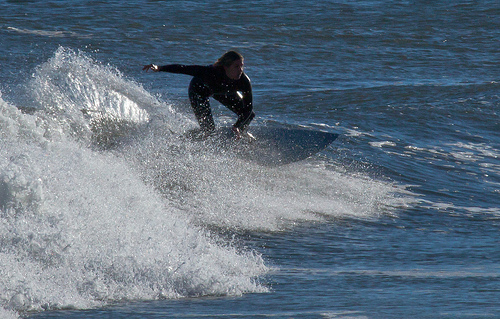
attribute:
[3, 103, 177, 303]
wave — breaking, large, white, splashing, frothy, crashing, swelling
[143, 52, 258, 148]
person — surfing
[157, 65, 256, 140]
suit — black, dark, wet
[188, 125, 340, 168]
surboard — blue, short, kneeling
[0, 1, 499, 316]
water — blue, undulating, calm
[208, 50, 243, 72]
hair — long, light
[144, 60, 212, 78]
arm — outstretched, out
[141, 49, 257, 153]
man — surfing, barefoot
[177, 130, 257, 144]
feet — spread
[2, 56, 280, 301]
waves — white